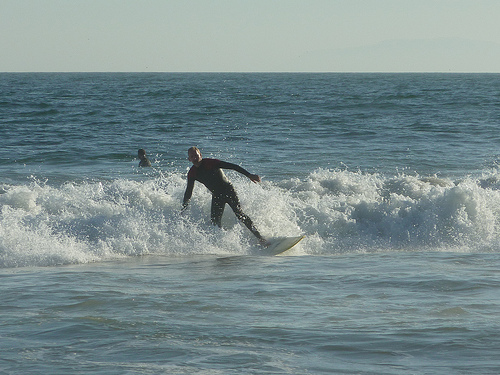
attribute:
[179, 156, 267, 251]
wetsuit — black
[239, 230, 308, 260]
surfboard — white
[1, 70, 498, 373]
water — sea water, calm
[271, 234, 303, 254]
surfboard — white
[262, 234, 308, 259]
surfboard — pointy, slanted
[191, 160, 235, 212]
wetsuit — black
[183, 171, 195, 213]
arm — extended